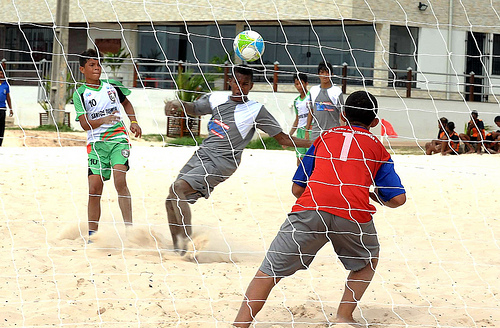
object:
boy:
[165, 64, 315, 262]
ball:
[231, 30, 266, 63]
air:
[194, 16, 211, 34]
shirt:
[292, 125, 406, 224]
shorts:
[177, 145, 241, 199]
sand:
[428, 190, 464, 244]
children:
[425, 110, 500, 155]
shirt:
[72, 79, 131, 138]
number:
[339, 132, 354, 162]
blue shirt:
[0, 82, 9, 108]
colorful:
[239, 35, 263, 52]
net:
[19, 31, 68, 116]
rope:
[154, 29, 193, 36]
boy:
[73, 48, 143, 244]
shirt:
[194, 92, 283, 181]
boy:
[232, 90, 406, 327]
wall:
[397, 100, 427, 131]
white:
[341, 149, 348, 159]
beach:
[2, 158, 51, 231]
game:
[63, 27, 413, 327]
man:
[0, 67, 14, 147]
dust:
[112, 223, 166, 249]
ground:
[0, 175, 499, 328]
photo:
[8, 17, 482, 300]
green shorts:
[87, 140, 131, 181]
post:
[50, 1, 70, 127]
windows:
[311, 24, 376, 64]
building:
[0, 0, 499, 145]